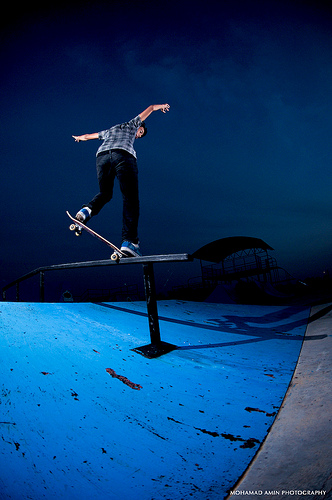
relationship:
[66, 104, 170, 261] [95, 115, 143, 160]
skater wearing shirt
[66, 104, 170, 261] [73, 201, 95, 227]
skater wearing sneaker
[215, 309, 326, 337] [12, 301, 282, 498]
shadow on ground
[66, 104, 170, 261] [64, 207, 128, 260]
skater riding skateboard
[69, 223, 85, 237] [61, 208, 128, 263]
wheels of skateboard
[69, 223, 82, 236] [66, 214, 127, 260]
wheels of skateboard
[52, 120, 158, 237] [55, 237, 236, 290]
skater on railing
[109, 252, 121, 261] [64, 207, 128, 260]
wheel on skateboard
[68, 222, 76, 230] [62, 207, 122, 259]
wheel on skateboard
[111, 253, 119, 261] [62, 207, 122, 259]
wheel on skateboard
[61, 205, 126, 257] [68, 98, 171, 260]
skateboard under boy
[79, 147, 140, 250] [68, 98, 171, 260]
pants on boy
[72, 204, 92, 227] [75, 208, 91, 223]
shoe on foot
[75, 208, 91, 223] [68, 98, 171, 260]
foot of boy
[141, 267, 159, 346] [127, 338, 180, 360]
pole with base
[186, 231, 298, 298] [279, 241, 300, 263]
structure in background